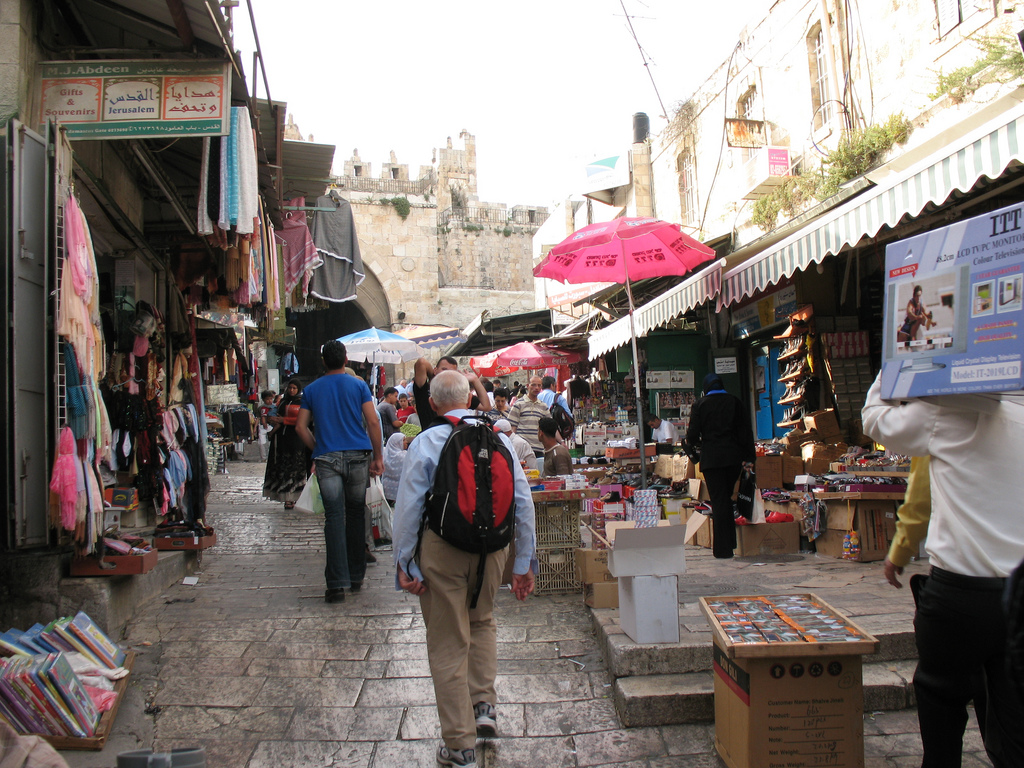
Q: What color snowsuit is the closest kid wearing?
A: Pink.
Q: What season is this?
A: Winter.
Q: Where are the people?
A: On a ski slope.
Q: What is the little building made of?
A: Wood.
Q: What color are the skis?
A: Yellow and grey.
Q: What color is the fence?
A: Orange.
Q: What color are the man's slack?
A: Brown.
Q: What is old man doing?
A: Walking.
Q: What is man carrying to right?
A: A box.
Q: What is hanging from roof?
A: Scarves.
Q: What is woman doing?
A: Walking.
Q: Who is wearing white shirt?
A: Man with box.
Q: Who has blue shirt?
A: Man with shopping bag.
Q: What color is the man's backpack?
A: Red and black.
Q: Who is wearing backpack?
A: Man in khakis.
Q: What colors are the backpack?
A: Red and black.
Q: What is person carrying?
A: Box.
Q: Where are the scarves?
A: On display.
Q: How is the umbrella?
A: Open.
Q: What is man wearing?
A: Backpack.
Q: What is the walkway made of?
A: Stone.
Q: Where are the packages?
A: In market.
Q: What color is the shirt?
A: Blue.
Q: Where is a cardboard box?
A: On the ground.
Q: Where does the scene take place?
A: At an outdoor market.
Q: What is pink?
A: An umbrella.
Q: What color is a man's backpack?
A: Red and black.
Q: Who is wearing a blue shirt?
A: One person.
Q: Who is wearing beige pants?
A: Man with backpack.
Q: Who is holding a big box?
A: Man in white shirt.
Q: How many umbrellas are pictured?
A: One.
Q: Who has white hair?
A: Man wearing backpack.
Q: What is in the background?
A: A building.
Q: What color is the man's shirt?
A: Blue.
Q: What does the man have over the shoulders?
A: Backpack.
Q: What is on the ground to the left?
A: Records.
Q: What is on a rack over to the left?
A: Clothes.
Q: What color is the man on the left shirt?
A: Blue.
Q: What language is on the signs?
A: Arabic.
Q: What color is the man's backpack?
A: Red and black.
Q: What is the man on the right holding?
A: Box.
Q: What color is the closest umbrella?
A: Pink.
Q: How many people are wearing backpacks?
A: 1.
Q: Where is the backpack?
A: Man's back.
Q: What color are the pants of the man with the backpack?
A: Tan.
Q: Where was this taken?
A: City street.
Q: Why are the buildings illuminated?
A: Sunny.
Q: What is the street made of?
A: Stone.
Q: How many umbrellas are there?
A: 2.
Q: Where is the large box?
A: On the man's shoulder.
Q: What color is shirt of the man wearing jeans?
A: Blue.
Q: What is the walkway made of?
A: Stones.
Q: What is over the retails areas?
A: Awnings.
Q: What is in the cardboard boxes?
A: Merchandise.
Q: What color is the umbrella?
A: Red.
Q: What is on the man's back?
A: Backpack.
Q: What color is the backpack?
A: Red and black.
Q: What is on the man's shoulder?
A: Box.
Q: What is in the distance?
A: Building.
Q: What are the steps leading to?
A: Vending area.